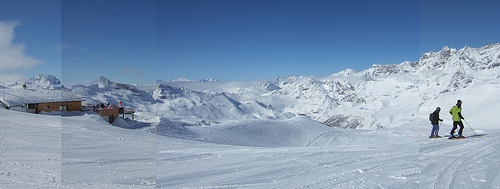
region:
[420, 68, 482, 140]
two people standing in the snow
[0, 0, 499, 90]
clear blue skies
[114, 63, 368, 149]
mountains of snow in the distance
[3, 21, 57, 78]
huge cloud in the sky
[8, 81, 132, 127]
small yellow structure in the snow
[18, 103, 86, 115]
windows on the side of the structure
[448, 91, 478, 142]
person wearing a yellow jacket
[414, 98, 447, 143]
person wearing a dark blue jacket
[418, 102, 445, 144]
arms are by his side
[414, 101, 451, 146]
man is slightly behind the other man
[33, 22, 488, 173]
Snow is on the ground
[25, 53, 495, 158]
Hills of snow are in the photo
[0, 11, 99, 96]
Clouds are in the sky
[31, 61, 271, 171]
A building is in the photo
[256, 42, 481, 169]
People are on skis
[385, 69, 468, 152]
One person has a backpack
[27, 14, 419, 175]
The photo was taken during the day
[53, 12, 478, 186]
The sky is blue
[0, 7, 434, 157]
Clouds are in the blue sky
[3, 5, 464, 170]
Clouds are in the sky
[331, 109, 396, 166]
part of some snow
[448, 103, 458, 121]
part of a green top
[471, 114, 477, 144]
part of a hooker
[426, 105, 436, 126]
part of a bag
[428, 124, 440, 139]
part of a jeans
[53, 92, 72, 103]
edge of a roof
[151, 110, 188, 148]
part of some snow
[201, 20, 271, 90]
part of the sky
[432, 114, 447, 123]
part of the right hand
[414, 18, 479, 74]
tip of some mountians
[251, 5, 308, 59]
part of the sky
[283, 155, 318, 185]
part of some snow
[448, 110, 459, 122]
part of a green jacket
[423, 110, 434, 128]
part of a bag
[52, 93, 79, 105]
edge of a house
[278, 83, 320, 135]
part of some snow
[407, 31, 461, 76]
tip of some mountains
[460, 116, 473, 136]
part of a hooker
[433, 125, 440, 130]
part of a trouser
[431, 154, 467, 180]
part off some footracks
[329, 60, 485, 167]
Two people in the snow.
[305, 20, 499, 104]
Mountains with snow on them.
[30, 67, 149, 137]
Building on the snow.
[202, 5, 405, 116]
Blue sky behind mountains.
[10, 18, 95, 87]
Clouds in the blue sky.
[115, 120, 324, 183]
Snow on the ground.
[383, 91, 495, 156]
People who are skiing.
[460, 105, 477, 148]
Man with ski pole.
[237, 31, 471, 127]
Blue sky behind white snowy mountains.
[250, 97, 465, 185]
Tracks in the snow.